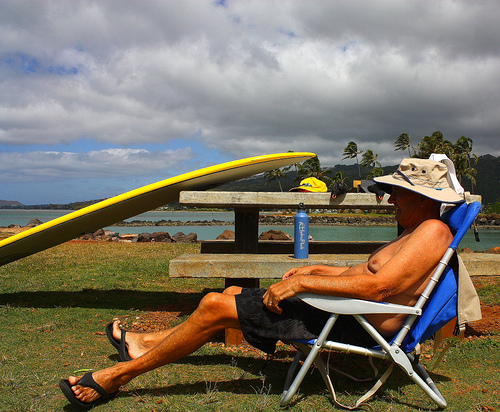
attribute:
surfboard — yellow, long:
[0, 151, 314, 267]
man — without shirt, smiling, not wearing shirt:
[68, 185, 455, 404]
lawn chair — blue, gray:
[279, 201, 482, 409]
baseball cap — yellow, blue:
[289, 176, 328, 194]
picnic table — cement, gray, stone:
[171, 190, 499, 346]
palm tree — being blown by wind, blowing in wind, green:
[266, 167, 282, 190]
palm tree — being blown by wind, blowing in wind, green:
[299, 156, 333, 191]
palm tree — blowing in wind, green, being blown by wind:
[343, 141, 362, 181]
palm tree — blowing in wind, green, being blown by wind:
[361, 151, 385, 178]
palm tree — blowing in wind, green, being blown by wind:
[395, 132, 412, 157]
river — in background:
[1, 207, 500, 251]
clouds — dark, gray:
[2, 1, 499, 166]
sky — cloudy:
[1, 0, 500, 206]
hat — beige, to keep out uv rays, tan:
[373, 159, 465, 204]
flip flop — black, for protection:
[59, 370, 118, 411]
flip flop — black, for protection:
[106, 323, 132, 361]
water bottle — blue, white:
[294, 203, 310, 259]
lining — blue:
[282, 202, 480, 356]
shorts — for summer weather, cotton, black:
[234, 286, 377, 355]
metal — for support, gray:
[280, 248, 455, 408]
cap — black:
[297, 202, 307, 210]